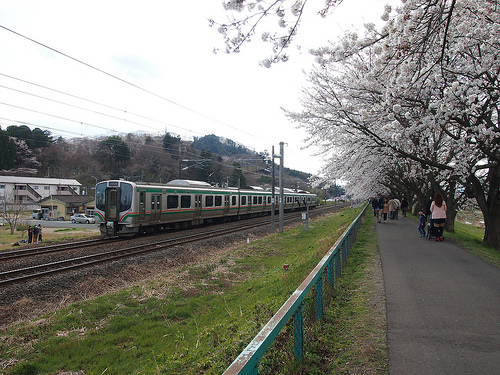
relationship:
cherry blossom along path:
[208, 0, 498, 208] [370, 200, 499, 375]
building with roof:
[35, 194, 93, 220] [30, 174, 104, 211]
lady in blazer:
[430, 193, 447, 242] [430, 201, 450, 221]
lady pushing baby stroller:
[430, 193, 447, 242] [426, 210, 436, 241]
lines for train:
[3, 20, 292, 189] [109, 163, 314, 245]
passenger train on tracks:
[93, 178, 319, 238] [1, 185, 349, 289]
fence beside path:
[211, 188, 388, 371] [355, 198, 483, 371]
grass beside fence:
[26, 190, 366, 370] [211, 188, 388, 371]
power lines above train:
[2, 26, 316, 188] [92, 168, 320, 235]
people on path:
[387, 200, 447, 224] [359, 200, 461, 372]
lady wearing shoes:
[430, 193, 447, 242] [408, 226, 462, 294]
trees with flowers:
[14, 118, 289, 192] [323, 26, 498, 148]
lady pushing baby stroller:
[430, 192, 449, 244] [426, 219, 446, 242]